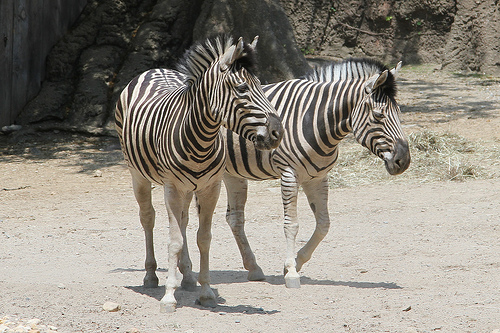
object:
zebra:
[178, 50, 418, 291]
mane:
[174, 32, 262, 88]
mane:
[297, 57, 398, 106]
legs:
[129, 171, 218, 309]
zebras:
[113, 34, 413, 308]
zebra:
[113, 35, 284, 313]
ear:
[220, 34, 260, 72]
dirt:
[0, 166, 499, 331]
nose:
[266, 115, 285, 145]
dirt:
[370, 194, 499, 288]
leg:
[178, 174, 330, 289]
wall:
[317, 86, 375, 125]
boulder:
[0, 1, 499, 141]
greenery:
[385, 16, 393, 22]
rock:
[103, 301, 121, 312]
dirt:
[78, 301, 225, 326]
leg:
[129, 163, 161, 293]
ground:
[0, 60, 499, 333]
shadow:
[108, 264, 403, 314]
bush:
[345, 127, 485, 182]